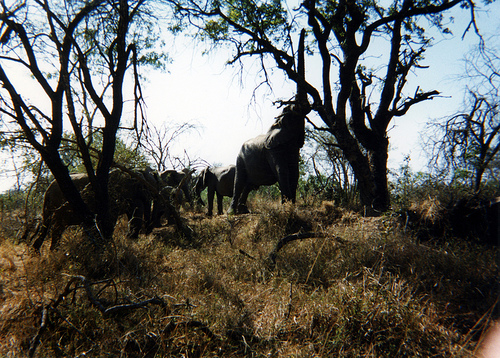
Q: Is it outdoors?
A: Yes, it is outdoors.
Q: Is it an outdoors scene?
A: Yes, it is outdoors.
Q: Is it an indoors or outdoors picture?
A: It is outdoors.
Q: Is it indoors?
A: No, it is outdoors.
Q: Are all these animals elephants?
A: Yes, all the animals are elephants.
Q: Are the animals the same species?
A: Yes, all the animals are elephants.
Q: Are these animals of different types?
A: No, all the animals are elephants.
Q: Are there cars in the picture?
A: No, there are no cars.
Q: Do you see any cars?
A: No, there are no cars.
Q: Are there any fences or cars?
A: No, there are no cars or fences.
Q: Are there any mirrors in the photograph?
A: No, there are no mirrors.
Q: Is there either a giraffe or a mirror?
A: No, there are no mirrors or giraffes.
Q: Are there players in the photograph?
A: No, there are no players.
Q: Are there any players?
A: No, there are no players.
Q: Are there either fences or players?
A: No, there are no players or fences.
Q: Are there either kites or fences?
A: No, there are no fences or kites.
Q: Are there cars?
A: No, there are no cars.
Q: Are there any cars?
A: No, there are no cars.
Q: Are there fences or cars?
A: No, there are no cars or fences.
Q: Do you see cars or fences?
A: No, there are no cars or fences.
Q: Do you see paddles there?
A: No, there are no paddles.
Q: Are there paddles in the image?
A: No, there are no paddles.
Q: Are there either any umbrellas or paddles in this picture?
A: No, there are no paddles or umbrellas.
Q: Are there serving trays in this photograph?
A: No, there are no serving trays.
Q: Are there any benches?
A: No, there are no benches.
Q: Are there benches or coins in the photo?
A: No, there are no benches or coins.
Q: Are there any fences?
A: No, there are no fences.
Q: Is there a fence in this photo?
A: No, there are no fences.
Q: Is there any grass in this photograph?
A: Yes, there is grass.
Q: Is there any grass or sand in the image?
A: Yes, there is grass.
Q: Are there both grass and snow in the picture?
A: No, there is grass but no snow.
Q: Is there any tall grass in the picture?
A: Yes, there is tall grass.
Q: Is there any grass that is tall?
A: Yes, there is grass that is tall.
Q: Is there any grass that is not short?
A: Yes, there is tall grass.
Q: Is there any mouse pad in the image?
A: No, there are no mouse pads.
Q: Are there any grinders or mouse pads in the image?
A: No, there are no mouse pads or grinders.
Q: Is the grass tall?
A: Yes, the grass is tall.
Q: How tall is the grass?
A: The grass is tall.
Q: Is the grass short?
A: No, the grass is tall.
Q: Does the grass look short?
A: No, the grass is tall.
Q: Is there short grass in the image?
A: No, there is grass but it is tall.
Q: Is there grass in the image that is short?
A: No, there is grass but it is tall.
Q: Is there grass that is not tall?
A: No, there is grass but it is tall.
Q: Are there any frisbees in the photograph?
A: No, there are no frisbees.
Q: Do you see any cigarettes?
A: No, there are no cigarettes.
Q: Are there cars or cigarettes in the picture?
A: No, there are no cigarettes or cars.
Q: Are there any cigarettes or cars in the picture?
A: No, there are no cigarettes or cars.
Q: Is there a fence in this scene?
A: No, there are no fences.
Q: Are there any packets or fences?
A: No, there are no fences or packets.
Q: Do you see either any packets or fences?
A: No, there are no fences or packets.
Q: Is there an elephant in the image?
A: Yes, there are elephants.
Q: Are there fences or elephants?
A: Yes, there are elephants.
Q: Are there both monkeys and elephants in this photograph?
A: No, there are elephants but no monkeys.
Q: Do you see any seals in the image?
A: No, there are no seals.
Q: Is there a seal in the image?
A: No, there are no seals.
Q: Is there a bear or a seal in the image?
A: No, there are no seals or bears.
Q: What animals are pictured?
A: The animals are elephants.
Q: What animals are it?
A: The animals are elephants.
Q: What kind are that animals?
A: These are elephants.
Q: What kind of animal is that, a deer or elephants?
A: These are elephants.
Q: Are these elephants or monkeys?
A: These are elephants.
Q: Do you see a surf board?
A: No, there are no surfboards.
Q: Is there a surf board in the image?
A: No, there are no surfboards.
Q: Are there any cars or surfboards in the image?
A: No, there are no surfboards or cars.